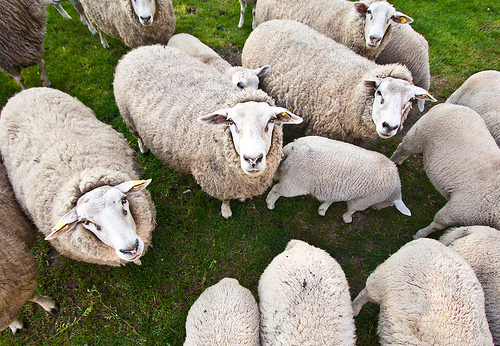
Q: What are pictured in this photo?
A: Sheep.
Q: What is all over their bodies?
A: Wool.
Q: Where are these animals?
A: In a pasture.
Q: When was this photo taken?
A: Daytime.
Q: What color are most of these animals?
A: White.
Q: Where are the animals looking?
A: At the camera.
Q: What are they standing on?
A: Grass.